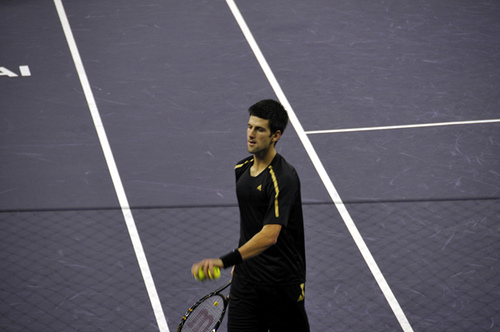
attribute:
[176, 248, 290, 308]
balls — chartreuse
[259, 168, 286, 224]
stripe — yellow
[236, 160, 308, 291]
shirt — black 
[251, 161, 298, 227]
stripe — yellow 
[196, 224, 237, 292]
balls — yellow 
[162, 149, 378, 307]
uniform — black , gold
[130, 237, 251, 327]
racket — gold, black, white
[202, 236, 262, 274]
wristband — black 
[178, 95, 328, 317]
player — WALKING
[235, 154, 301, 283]
tee shirt — BLACK, SHORT SLEEVED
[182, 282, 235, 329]
racket — yellow, black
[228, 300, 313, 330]
shorts — black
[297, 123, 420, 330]
stripe — white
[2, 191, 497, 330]
fence — chain link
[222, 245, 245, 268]
wristband — black  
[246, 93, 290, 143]
hair — short , black 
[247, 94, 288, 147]
hair — dark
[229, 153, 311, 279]
shirt — black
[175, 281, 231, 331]
racket — black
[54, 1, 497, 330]
lines — white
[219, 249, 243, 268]
wristband — black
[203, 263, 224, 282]
ball — yellow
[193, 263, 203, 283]
ball — yellow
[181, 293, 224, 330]
strings — white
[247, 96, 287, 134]
hair — black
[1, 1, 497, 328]
ground — black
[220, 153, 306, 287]
top — black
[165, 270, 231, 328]
racket — black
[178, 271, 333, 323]
shorts — black 